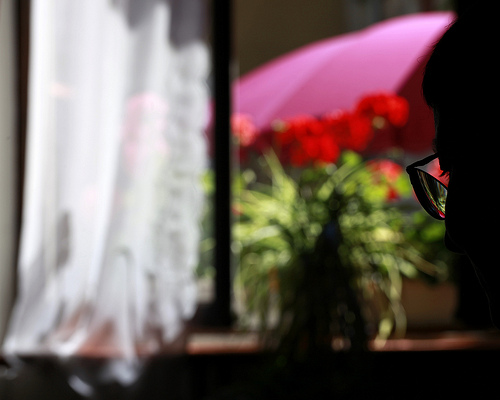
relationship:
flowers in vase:
[233, 89, 451, 363] [235, 236, 282, 328]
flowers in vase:
[233, 89, 451, 363] [265, 262, 457, 334]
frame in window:
[204, 2, 243, 331] [18, 2, 226, 325]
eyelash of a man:
[437, 163, 445, 178] [417, 5, 499, 332]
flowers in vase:
[233, 89, 451, 363] [225, 242, 285, 332]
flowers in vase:
[233, 89, 451, 363] [256, 247, 382, 399]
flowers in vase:
[233, 89, 451, 363] [351, 246, 411, 337]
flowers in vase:
[233, 89, 451, 363] [284, 224, 366, 363]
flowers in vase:
[233, 89, 451, 363] [264, 168, 390, 370]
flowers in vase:
[239, 87, 409, 301] [288, 185, 364, 374]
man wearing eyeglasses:
[406, 5, 499, 331] [408, 153, 457, 219]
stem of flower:
[343, 176, 383, 267] [336, 90, 419, 339]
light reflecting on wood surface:
[173, 325, 477, 352] [171, 338, 472, 353]